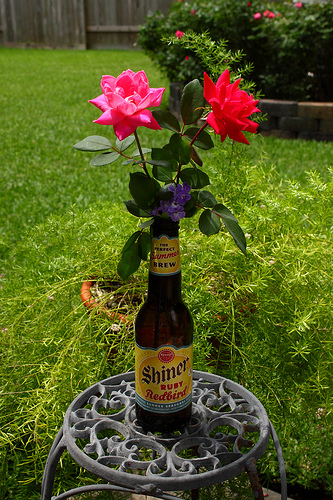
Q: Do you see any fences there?
A: Yes, there is a fence.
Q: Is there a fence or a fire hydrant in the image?
A: Yes, there is a fence.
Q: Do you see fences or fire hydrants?
A: Yes, there is a fence.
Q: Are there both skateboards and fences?
A: No, there is a fence but no skateboards.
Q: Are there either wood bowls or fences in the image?
A: Yes, there is a wood fence.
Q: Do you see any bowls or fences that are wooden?
A: Yes, the fence is wooden.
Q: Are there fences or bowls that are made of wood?
A: Yes, the fence is made of wood.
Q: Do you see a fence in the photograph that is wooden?
A: Yes, there is a fence that is wooden.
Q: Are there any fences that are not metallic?
A: Yes, there is a wooden fence.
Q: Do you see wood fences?
A: Yes, there is a fence that is made of wood.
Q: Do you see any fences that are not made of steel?
A: Yes, there is a fence that is made of wood.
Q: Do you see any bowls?
A: No, there are no bowls.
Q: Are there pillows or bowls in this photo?
A: No, there are no bowls or pillows.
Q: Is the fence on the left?
A: Yes, the fence is on the left of the image.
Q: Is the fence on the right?
A: No, the fence is on the left of the image.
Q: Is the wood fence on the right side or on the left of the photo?
A: The fence is on the left of the image.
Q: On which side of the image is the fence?
A: The fence is on the left of the image.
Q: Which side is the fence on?
A: The fence is on the left of the image.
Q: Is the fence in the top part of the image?
A: Yes, the fence is in the top of the image.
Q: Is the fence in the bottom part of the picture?
A: No, the fence is in the top of the image.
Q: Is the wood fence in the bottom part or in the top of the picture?
A: The fence is in the top of the image.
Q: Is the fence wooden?
A: Yes, the fence is wooden.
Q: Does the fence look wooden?
A: Yes, the fence is wooden.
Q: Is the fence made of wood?
A: Yes, the fence is made of wood.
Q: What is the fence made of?
A: The fence is made of wood.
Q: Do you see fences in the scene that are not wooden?
A: No, there is a fence but it is wooden.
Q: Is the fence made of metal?
A: No, the fence is made of wood.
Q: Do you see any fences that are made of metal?
A: No, there is a fence but it is made of wood.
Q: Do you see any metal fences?
A: No, there is a fence but it is made of wood.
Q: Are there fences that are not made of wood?
A: No, there is a fence but it is made of wood.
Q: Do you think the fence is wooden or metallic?
A: The fence is wooden.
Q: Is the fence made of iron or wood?
A: The fence is made of wood.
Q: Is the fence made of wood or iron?
A: The fence is made of wood.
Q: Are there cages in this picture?
A: No, there are no cages.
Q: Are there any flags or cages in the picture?
A: No, there are no cages or flags.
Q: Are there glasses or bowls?
A: No, there are no bowls or glasses.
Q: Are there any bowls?
A: No, there are no bowls.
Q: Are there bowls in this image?
A: No, there are no bowls.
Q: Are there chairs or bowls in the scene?
A: No, there are no bowls or chairs.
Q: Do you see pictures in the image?
A: No, there are no pictures.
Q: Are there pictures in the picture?
A: No, there are no pictures.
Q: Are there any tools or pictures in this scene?
A: No, there are no pictures or tools.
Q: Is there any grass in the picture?
A: Yes, there is grass.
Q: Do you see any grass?
A: Yes, there is grass.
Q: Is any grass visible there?
A: Yes, there is grass.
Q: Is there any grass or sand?
A: Yes, there is grass.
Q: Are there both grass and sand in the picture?
A: No, there is grass but no sand.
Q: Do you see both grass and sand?
A: No, there is grass but no sand.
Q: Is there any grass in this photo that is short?
A: Yes, there is short grass.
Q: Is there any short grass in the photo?
A: Yes, there is short grass.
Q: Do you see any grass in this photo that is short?
A: Yes, there is grass that is short.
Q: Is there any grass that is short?
A: Yes, there is grass that is short.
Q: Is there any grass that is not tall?
A: Yes, there is short grass.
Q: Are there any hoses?
A: No, there are no hoses.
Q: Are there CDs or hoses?
A: No, there are no hoses or cds.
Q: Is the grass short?
A: Yes, the grass is short.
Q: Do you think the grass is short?
A: Yes, the grass is short.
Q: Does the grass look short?
A: Yes, the grass is short.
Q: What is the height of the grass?
A: The grass is short.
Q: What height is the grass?
A: The grass is short.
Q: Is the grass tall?
A: No, the grass is short.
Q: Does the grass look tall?
A: No, the grass is short.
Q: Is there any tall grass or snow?
A: No, there is grass but it is short.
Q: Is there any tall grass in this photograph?
A: No, there is grass but it is short.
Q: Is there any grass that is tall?
A: No, there is grass but it is short.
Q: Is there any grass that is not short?
A: No, there is grass but it is short.